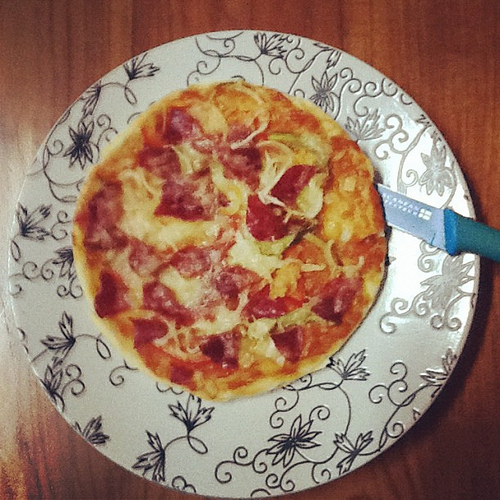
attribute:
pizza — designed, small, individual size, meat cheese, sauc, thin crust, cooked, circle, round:
[70, 82, 388, 405]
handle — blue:
[444, 207, 499, 261]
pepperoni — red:
[152, 179, 212, 220]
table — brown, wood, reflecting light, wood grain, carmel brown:
[3, 1, 499, 498]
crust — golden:
[229, 302, 373, 398]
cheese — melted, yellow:
[117, 164, 217, 251]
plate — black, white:
[62, 51, 159, 170]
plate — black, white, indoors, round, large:
[9, 32, 483, 500]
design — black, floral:
[216, 347, 461, 498]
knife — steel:
[375, 180, 499, 259]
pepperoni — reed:
[128, 237, 171, 276]